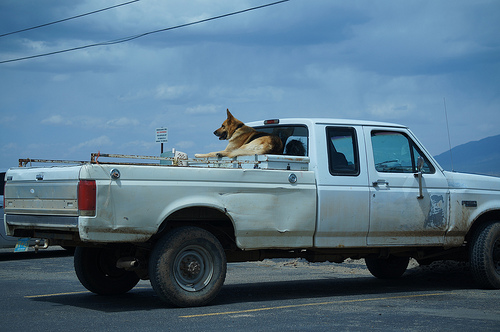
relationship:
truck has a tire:
[2, 116, 491, 308] [148, 228, 226, 304]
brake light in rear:
[77, 180, 96, 210] [5, 163, 95, 242]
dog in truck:
[194, 109, 281, 158] [2, 116, 491, 308]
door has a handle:
[364, 126, 448, 250] [374, 180, 390, 188]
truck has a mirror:
[2, 116, 491, 308] [416, 157, 423, 178]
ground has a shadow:
[1, 250, 498, 331] [33, 277, 499, 315]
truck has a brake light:
[2, 116, 491, 308] [77, 180, 96, 210]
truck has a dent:
[2, 116, 491, 308] [274, 186, 292, 231]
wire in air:
[1, 1, 285, 66] [2, 3, 499, 331]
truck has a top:
[2, 116, 491, 308] [239, 119, 443, 173]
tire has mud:
[148, 228, 226, 304] [147, 238, 174, 308]